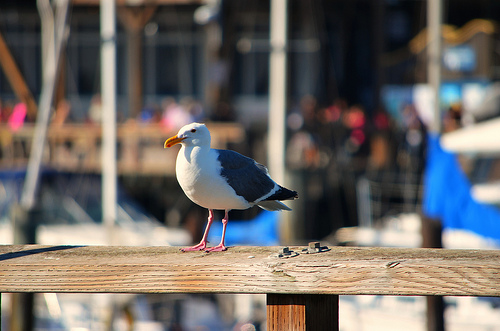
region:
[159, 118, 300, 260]
Bird on the wood.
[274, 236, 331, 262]
Bolts on the wood.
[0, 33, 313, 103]
Windows in the back.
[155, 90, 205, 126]
People sitting down.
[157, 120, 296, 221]
Gray, white, and black feathers.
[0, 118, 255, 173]
Wood rail on the building.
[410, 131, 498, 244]
Blue material in the background.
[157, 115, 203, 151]
Orange beak on the bird.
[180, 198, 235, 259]
Pink legs on the bird.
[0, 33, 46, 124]
Wood support beam in the back.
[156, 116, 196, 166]
the beak of a bird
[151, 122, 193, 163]
a orange beak of a bird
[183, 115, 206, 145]
thr eye of a bird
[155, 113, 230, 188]
the head of a bird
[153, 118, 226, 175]
the white head of a bird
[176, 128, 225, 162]
the neck of a bird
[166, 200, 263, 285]
the legs of a bird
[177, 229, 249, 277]
the feet of a bird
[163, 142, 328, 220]
the wing of a bird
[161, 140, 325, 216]
the feathers of a bird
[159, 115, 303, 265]
a seagull perched on a wooden fence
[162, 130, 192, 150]
orange beak of a seagul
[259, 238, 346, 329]
bolts secure a fence post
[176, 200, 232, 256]
pink legs and feet of a seagull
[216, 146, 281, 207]
grey feathered wing of a seagull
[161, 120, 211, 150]
white feathered head of a seagull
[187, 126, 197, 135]
small eye of a seagull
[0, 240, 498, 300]
wooden top bar of a fence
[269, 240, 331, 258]
metal bolts on a wooden fence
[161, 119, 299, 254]
seagull has webbed feet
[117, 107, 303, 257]
seagull that is standing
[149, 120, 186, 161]
bird has orange beak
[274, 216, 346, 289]
screws on the railing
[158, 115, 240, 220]
seagull has white face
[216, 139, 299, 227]
bird has gray wings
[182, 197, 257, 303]
bird has webbed feet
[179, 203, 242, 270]
bird has orange feet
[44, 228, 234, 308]
railing is brown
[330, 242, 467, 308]
railing is made of wood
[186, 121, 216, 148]
bird has black eye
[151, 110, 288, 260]
bird standing on the wooden post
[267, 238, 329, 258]
two bolts in the wood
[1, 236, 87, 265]
shadow on the wood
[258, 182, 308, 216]
black and gray feathers on the tail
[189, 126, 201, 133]
small black eye on the side of the face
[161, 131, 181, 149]
bright orange beak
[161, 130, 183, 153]
beak is slightly curved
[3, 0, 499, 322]
background is blurry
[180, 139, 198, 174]
shadow on the bird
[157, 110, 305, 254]
black, white, and gray bird